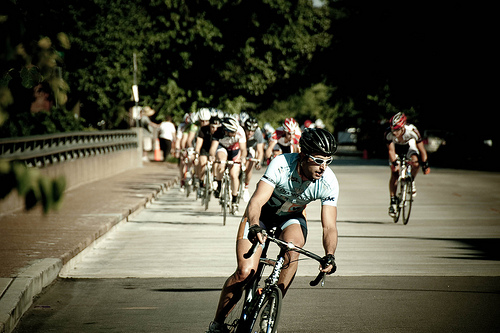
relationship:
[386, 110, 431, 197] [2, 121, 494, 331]
people on bridge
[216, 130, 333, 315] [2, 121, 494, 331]
bicyclist on bridge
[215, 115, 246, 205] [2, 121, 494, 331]
people on bridge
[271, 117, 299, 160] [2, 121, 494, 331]
people on bridge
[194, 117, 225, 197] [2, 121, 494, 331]
people on bridge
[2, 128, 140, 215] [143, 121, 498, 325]
railing on bridge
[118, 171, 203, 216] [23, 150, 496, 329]
shadows on ground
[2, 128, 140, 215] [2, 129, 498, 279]
railing on bridge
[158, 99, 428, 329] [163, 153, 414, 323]
people riding bicycles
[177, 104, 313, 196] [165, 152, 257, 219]
people on bicycle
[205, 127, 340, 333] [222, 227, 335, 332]
bicyclist on bicycle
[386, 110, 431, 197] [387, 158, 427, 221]
people on bicycle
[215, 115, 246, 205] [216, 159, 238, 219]
people on bicycle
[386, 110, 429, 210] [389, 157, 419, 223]
people on bicycle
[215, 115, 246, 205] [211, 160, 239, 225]
people on bicycle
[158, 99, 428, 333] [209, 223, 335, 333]
people riding bicycle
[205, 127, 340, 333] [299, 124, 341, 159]
bicyclist wearing helmet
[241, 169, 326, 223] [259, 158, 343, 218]
dark graphics on shirt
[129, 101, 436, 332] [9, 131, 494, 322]
racers riding over bridge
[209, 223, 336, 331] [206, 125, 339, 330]
bicycle ridden by racer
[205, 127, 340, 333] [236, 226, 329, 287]
bicyclist holding handlebar